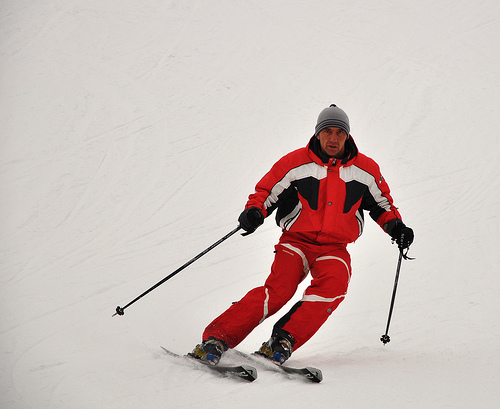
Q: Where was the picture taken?
A: Ski slope.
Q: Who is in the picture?
A: A man.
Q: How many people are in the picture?
A: One.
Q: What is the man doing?
A: Skiing.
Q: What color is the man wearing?
A: Red.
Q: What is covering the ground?
A: Snow.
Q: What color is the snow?
A: White.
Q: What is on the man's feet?
A: Skiis.